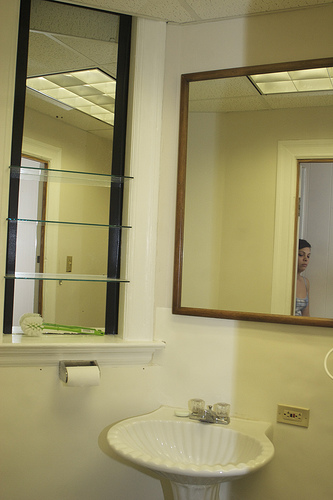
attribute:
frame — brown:
[173, 58, 331, 328]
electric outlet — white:
[279, 405, 310, 430]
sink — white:
[105, 403, 275, 499]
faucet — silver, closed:
[186, 404, 229, 425]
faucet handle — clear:
[188, 399, 209, 412]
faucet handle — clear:
[217, 403, 231, 417]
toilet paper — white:
[65, 366, 102, 387]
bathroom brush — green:
[22, 314, 106, 338]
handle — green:
[45, 325, 108, 338]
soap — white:
[171, 407, 190, 421]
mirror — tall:
[13, 1, 122, 336]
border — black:
[7, 3, 133, 342]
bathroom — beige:
[4, 1, 333, 498]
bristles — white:
[20, 313, 43, 338]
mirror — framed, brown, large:
[168, 54, 328, 339]